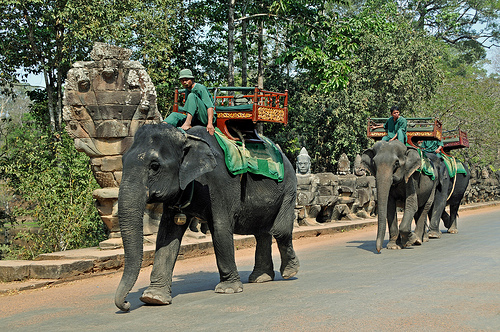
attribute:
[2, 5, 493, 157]
leaves — green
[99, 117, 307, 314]
elephant — giant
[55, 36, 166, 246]
statue — cement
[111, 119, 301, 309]
elephant — large, very sad, adult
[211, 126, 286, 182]
blanket — green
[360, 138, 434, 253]
elephant — adult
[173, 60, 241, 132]
man — young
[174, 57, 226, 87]
hat — green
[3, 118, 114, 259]
trees — green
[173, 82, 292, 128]
cart — wooden, furniture like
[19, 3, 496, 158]
trees — tall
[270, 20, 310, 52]
leaves — green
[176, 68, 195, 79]
hat — green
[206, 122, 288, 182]
blanket — green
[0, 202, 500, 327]
street — asphalt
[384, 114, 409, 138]
shirt — green